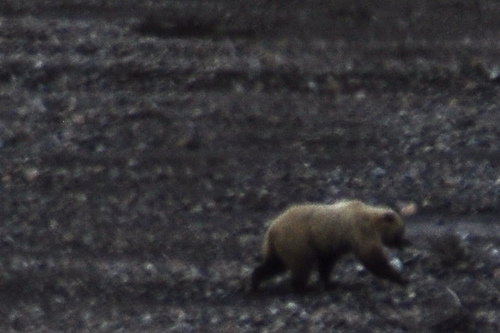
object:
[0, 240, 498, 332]
path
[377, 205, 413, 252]
head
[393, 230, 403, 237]
eye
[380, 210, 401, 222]
ear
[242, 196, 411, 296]
grapefruit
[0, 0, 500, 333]
field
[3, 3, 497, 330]
ground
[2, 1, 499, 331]
dirt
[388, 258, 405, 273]
rock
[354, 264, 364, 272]
rock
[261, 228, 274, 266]
bear tail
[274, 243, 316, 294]
legs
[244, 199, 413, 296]
bear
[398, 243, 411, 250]
mouth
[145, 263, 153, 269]
rock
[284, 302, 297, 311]
rock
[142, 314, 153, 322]
rock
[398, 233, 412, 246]
muzzle